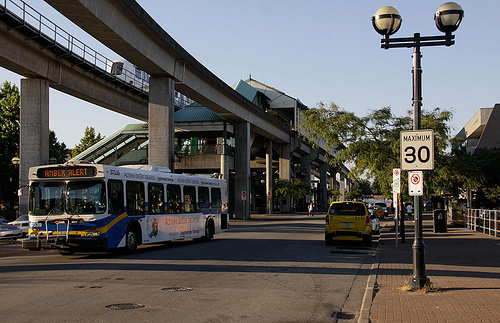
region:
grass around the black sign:
[390, 270, 448, 307]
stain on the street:
[312, 300, 352, 321]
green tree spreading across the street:
[297, 94, 451, 196]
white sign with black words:
[383, 119, 449, 175]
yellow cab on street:
[318, 193, 383, 241]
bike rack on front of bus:
[23, 211, 95, 244]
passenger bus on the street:
[36, 153, 247, 250]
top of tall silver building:
[454, 93, 498, 146]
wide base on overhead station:
[134, 84, 196, 137]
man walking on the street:
[398, 198, 425, 220]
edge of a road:
[366, 253, 378, 288]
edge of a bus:
[105, 193, 108, 225]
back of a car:
[336, 213, 346, 229]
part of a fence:
[476, 201, 492, 217]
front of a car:
[70, 215, 87, 232]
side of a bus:
[170, 220, 184, 241]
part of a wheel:
[120, 231, 132, 259]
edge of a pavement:
[376, 242, 381, 290]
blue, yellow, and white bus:
[17, 153, 237, 255]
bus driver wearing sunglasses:
[72, 191, 102, 216]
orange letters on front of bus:
[34, 164, 103, 184]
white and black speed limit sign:
[399, 127, 436, 173]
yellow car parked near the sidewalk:
[322, 199, 384, 254]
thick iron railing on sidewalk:
[462, 206, 497, 241]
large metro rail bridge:
[31, 74, 323, 230]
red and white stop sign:
[264, 191, 277, 216]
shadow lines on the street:
[236, 221, 308, 292]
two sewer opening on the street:
[107, 279, 202, 320]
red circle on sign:
[408, 173, 430, 186]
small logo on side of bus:
[143, 215, 167, 243]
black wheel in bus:
[194, 210, 224, 250]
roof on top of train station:
[232, 54, 323, 121]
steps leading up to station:
[83, 129, 196, 169]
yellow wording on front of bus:
[23, 156, 115, 181]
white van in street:
[359, 186, 396, 211]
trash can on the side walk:
[426, 207, 449, 234]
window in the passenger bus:
[111, 171, 153, 216]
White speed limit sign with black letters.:
[400, 130, 432, 168]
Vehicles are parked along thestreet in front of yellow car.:
[326, 194, 388, 244]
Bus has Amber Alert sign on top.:
[30, 165, 100, 255]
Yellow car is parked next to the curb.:
[322, 197, 379, 240]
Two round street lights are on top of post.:
[372, 0, 463, 46]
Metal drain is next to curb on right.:
[330, 310, 365, 318]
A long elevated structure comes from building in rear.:
[153, 16, 354, 163]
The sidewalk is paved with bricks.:
[372, 211, 492, 313]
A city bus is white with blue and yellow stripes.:
[21, 163, 226, 254]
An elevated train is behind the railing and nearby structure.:
[108, 55, 193, 111]